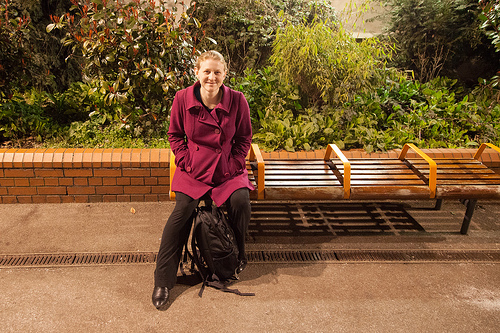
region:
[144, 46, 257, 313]
THE WOMAN IS SITTING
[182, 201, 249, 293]
THE WOMAN HAS A BACKPACK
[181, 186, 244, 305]
THE BACKPACK IS BLACK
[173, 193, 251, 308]
THE BACKPACK IS ON THE GROUND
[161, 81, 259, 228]
THE WOMAN IS WEARING A JACKET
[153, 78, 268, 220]
THE JACKET IS RED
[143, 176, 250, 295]
THE WOMAN IS WEARING BLACK PANTS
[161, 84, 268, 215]
THE WOMAN HAS HER HANDS IN HER POCKETS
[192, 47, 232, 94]
THE WOMAN IS SMILING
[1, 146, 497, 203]
THE WALL IS BRICK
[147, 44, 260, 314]
woman sitting outside on a bench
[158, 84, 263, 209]
maroon jacket on a woman outside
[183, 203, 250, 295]
bookbag next to a woman outside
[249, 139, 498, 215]
bench outside near trees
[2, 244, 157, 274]
grate on the ground outside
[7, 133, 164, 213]
brick wall outside near trees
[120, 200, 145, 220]
leaf on cement outside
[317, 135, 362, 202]
handle on a bench outside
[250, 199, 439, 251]
shadow of a bench outside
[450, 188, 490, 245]
leg of a bench outside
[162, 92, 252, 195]
the jacket is red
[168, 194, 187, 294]
the pants are black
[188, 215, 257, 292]
the bag is black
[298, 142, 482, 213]
the chair is wooden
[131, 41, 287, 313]
the woman is sitted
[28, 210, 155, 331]
the ground is brown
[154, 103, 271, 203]
her hands are in the pocket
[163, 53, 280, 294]
the woman is smilling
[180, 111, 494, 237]
four sitting space are on the bench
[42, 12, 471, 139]
vegetation is on the ground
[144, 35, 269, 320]
the woman is sitting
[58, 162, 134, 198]
the wall is brick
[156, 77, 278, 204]
the coat is pink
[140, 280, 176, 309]
the shoe is black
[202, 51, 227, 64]
the hair is blonde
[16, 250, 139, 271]
the vent is on the ground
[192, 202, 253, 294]
the backpack is black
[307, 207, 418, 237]
the shadow is on the ground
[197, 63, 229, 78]
the girl has eyes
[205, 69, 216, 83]
the woman has a nose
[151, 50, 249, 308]
A woman in a pink jacket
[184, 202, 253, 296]
A black back pack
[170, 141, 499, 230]
A long wooden bench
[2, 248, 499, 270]
A drain on the ground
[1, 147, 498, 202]
A small brick wall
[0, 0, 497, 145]
A small wooded area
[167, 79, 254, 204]
A pink jacket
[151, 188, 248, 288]
A pair of black pants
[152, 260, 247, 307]
A pair of black shoes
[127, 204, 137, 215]
A leaf on the ground